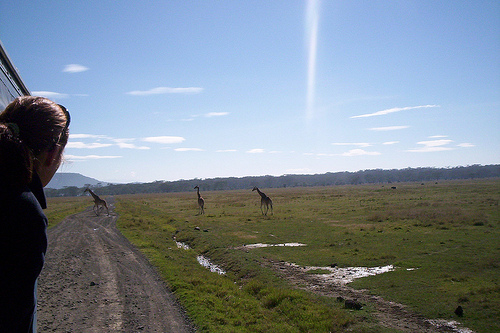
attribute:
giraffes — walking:
[84, 185, 274, 216]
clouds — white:
[61, 133, 191, 163]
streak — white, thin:
[300, 0, 322, 132]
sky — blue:
[0, 1, 498, 186]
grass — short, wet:
[44, 186, 500, 333]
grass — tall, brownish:
[35, 195, 101, 237]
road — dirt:
[31, 200, 190, 332]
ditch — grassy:
[122, 229, 364, 332]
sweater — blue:
[3, 176, 47, 333]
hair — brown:
[0, 96, 69, 198]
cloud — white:
[353, 102, 437, 125]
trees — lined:
[43, 163, 499, 196]